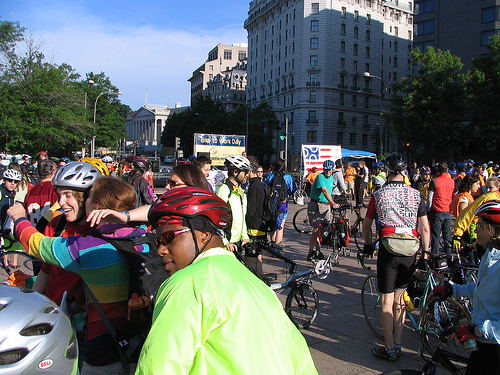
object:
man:
[133, 183, 319, 374]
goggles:
[145, 226, 202, 246]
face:
[150, 226, 203, 274]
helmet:
[147, 188, 231, 229]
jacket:
[132, 246, 320, 372]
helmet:
[50, 160, 105, 189]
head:
[53, 163, 101, 222]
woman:
[32, 158, 157, 326]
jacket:
[11, 218, 148, 345]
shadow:
[321, 306, 359, 354]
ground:
[301, 274, 341, 293]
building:
[243, 0, 420, 171]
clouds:
[85, 32, 182, 71]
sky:
[115, 1, 200, 34]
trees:
[1, 32, 103, 157]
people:
[213, 155, 253, 261]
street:
[262, 228, 354, 301]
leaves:
[39, 139, 59, 148]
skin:
[384, 174, 408, 181]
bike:
[309, 203, 355, 251]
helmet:
[382, 156, 408, 173]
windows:
[304, 51, 324, 66]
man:
[307, 159, 338, 263]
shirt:
[308, 174, 337, 203]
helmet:
[320, 160, 337, 170]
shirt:
[368, 181, 429, 239]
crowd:
[6, 136, 303, 373]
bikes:
[225, 238, 325, 331]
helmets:
[48, 160, 101, 191]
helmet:
[225, 155, 253, 172]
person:
[0, 168, 23, 251]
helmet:
[3, 168, 22, 181]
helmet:
[75, 155, 107, 175]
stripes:
[76, 261, 120, 296]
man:
[362, 152, 430, 363]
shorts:
[373, 247, 418, 293]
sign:
[303, 143, 343, 180]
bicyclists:
[1, 168, 499, 373]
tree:
[64, 72, 126, 151]